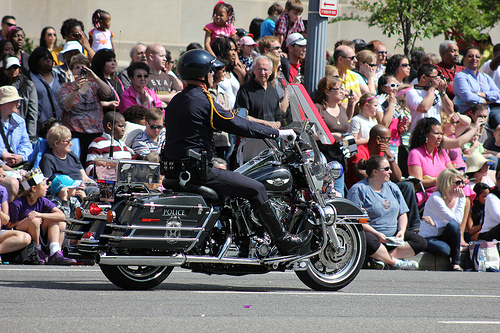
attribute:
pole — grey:
[299, 2, 344, 112]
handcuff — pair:
[176, 169, 195, 189]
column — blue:
[303, 0, 328, 102]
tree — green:
[328, 1, 498, 59]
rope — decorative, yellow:
[195, 83, 238, 132]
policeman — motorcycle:
[159, 47, 321, 254]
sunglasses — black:
[134, 69, 148, 80]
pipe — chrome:
[91, 245, 191, 272]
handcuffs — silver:
[172, 167, 193, 187]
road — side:
[1, 264, 499, 331]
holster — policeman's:
[201, 143, 214, 189]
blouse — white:
[420, 192, 470, 238]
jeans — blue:
[430, 224, 466, 262]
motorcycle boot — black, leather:
[253, 197, 312, 256]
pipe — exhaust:
[91, 240, 201, 285]